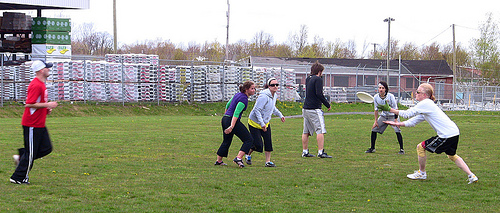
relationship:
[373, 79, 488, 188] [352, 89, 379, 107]
girl about to catch frisbee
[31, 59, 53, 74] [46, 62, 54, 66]
cap with bill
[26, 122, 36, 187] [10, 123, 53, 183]
stripe of pants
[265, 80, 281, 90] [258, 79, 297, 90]
shades cover eyes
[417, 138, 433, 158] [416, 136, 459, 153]
patch on shorts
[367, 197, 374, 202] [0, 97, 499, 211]
yellow spot in grass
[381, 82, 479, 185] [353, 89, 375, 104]
girl catching frisbee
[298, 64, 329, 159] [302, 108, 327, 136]
man in shorts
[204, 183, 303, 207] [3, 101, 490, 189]
grass in field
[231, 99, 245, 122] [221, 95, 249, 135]
sleeve on arm